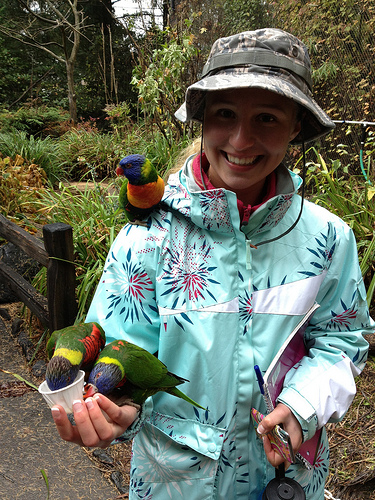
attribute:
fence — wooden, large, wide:
[4, 216, 88, 306]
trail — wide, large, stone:
[18, 404, 59, 489]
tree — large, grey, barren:
[8, 12, 129, 128]